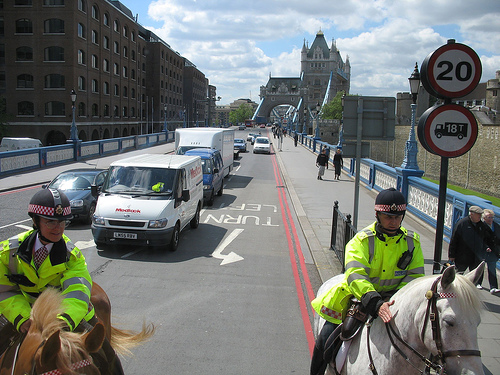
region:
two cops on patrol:
[13, 109, 441, 355]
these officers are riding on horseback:
[19, 165, 435, 374]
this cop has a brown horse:
[14, 178, 125, 370]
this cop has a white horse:
[307, 166, 494, 363]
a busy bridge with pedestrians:
[247, 31, 407, 144]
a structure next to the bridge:
[268, 32, 341, 99]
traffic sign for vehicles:
[407, 27, 488, 164]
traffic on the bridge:
[79, 103, 277, 246]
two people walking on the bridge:
[456, 196, 498, 273]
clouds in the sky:
[159, 8, 271, 79]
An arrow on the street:
[211, 227, 248, 265]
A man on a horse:
[311, 188, 488, 373]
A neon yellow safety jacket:
[315, 230, 422, 319]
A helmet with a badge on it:
[375, 187, 407, 211]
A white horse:
[314, 264, 488, 374]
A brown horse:
[0, 278, 154, 373]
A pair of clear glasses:
[36, 216, 71, 228]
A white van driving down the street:
[92, 157, 203, 248]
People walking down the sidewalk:
[269, 125, 344, 182]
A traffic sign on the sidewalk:
[419, 38, 481, 277]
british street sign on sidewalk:
[408, 22, 479, 283]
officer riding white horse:
[301, 165, 491, 367]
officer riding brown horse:
[1, 183, 138, 372]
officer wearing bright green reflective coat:
[331, 169, 432, 354]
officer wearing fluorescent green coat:
[6, 178, 126, 358]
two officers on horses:
[1, 183, 498, 372]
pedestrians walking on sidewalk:
[272, 110, 355, 197]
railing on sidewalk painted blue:
[320, 125, 481, 227]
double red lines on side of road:
[264, 145, 324, 348]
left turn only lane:
[196, 117, 291, 355]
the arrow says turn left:
[219, 196, 291, 274]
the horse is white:
[314, 280, 483, 373]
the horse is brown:
[37, 276, 135, 363]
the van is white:
[94, 148, 207, 251]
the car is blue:
[192, 145, 232, 195]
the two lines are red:
[281, 213, 310, 292]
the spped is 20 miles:
[431, 47, 479, 96]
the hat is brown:
[466, 205, 483, 216]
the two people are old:
[460, 205, 498, 303]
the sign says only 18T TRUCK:
[428, 106, 475, 148]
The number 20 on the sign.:
[436, 57, 474, 81]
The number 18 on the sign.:
[445, 123, 457, 134]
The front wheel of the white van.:
[170, 228, 180, 248]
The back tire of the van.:
[195, 201, 200, 223]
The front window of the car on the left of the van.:
[50, 173, 90, 190]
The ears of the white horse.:
[438, 268, 484, 284]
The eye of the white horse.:
[442, 318, 452, 328]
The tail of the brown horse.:
[112, 321, 156, 358]